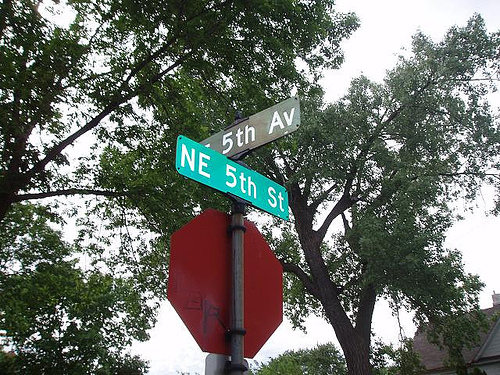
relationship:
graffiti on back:
[179, 298, 250, 356] [150, 238, 268, 364]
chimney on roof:
[468, 289, 497, 301] [406, 323, 488, 369]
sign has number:
[168, 84, 275, 203] [219, 165, 244, 188]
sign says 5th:
[168, 84, 275, 203] [206, 169, 290, 217]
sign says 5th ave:
[168, 84, 275, 203] [207, 117, 329, 160]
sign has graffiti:
[168, 84, 275, 203] [179, 298, 250, 356]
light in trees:
[321, 38, 367, 77] [104, 50, 262, 148]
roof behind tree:
[406, 323, 488, 369] [141, 9, 494, 368]